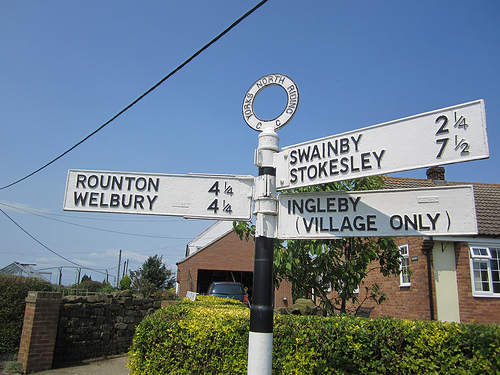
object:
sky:
[0, 0, 497, 286]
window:
[468, 244, 499, 301]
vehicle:
[202, 278, 251, 307]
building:
[295, 174, 500, 321]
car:
[205, 279, 252, 307]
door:
[193, 267, 253, 305]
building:
[173, 179, 294, 311]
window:
[394, 243, 412, 289]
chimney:
[425, 165, 445, 179]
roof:
[358, 176, 500, 235]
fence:
[53, 289, 179, 367]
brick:
[489, 317, 500, 323]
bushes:
[117, 296, 497, 371]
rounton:
[74, 172, 160, 192]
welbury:
[72, 190, 158, 211]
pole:
[239, 71, 300, 375]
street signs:
[58, 163, 255, 226]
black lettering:
[148, 175, 162, 194]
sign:
[273, 181, 483, 243]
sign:
[275, 95, 490, 191]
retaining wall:
[17, 289, 145, 369]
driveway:
[40, 349, 127, 375]